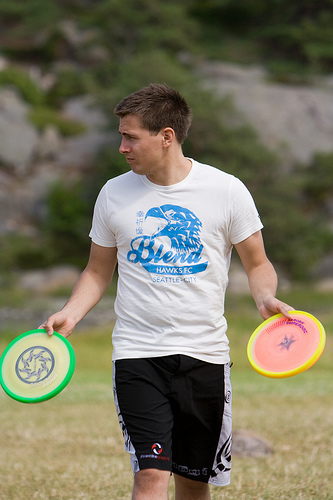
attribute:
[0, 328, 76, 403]
frisbee — green, yellow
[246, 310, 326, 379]
frisbee — yellow, orange, pink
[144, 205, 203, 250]
hawk — blue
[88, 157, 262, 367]
shirt — blue, white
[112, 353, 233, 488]
shorts — black, white, red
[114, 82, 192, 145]
hair — brown, short, dark brown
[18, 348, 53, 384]
sun shape — strange, circular, blue, black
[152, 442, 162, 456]
logo — red, white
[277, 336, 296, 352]
design — odd shaped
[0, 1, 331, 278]
foliage — green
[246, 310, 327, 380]
trim — yellow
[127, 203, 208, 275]
design — blue